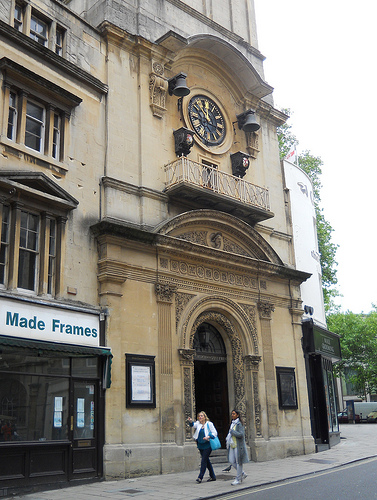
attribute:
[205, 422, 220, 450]
purse — blue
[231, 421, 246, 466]
coat — gray, long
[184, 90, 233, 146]
clock — black, gold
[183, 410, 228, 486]
woman — blonde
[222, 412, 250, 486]
woman — dark haired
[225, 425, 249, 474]
clothes — grey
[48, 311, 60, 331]
f — blue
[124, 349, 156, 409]
frame — large, black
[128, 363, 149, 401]
paper — white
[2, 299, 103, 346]
sign — white, long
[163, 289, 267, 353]
archway — large, concrete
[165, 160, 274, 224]
balcony — brown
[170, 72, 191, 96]
bell — black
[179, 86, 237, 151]
clock face — black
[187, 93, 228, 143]
numbers — gold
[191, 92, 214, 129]
hands — gold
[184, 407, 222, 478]
woman — pointing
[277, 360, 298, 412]
sign — black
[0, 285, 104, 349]
sign — white, blue